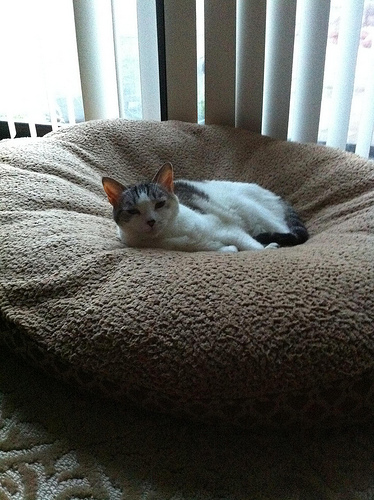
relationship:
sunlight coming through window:
[0, 3, 140, 129] [0, 0, 371, 160]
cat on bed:
[100, 162, 309, 254] [4, 114, 368, 430]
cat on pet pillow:
[100, 162, 309, 254] [0, 116, 372, 405]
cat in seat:
[100, 162, 309, 254] [2, 111, 371, 434]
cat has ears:
[101, 162, 308, 249] [98, 157, 178, 201]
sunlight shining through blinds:
[0, 3, 135, 128] [2, 2, 371, 139]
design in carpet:
[2, 434, 110, 497] [2, 364, 371, 497]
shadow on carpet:
[75, 366, 370, 497] [2, 364, 371, 497]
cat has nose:
[100, 162, 309, 254] [141, 213, 162, 229]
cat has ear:
[100, 162, 309, 254] [98, 176, 123, 202]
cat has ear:
[100, 162, 309, 254] [151, 160, 180, 191]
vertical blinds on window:
[135, 18, 368, 147] [2, 18, 370, 135]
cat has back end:
[100, 162, 309, 254] [241, 173, 306, 249]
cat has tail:
[100, 162, 309, 254] [252, 205, 309, 249]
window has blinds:
[2, 0, 371, 137] [72, 1, 369, 115]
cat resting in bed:
[100, 162, 309, 254] [4, 114, 368, 430]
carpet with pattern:
[4, 383, 369, 496] [2, 436, 107, 495]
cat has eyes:
[100, 162, 309, 254] [123, 196, 169, 220]